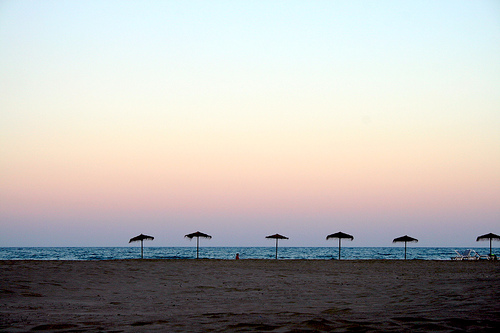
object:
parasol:
[265, 233, 289, 259]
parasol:
[129, 233, 154, 259]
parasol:
[184, 231, 212, 259]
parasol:
[326, 232, 354, 261]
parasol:
[392, 234, 418, 260]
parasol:
[476, 233, 500, 260]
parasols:
[129, 230, 500, 260]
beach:
[0, 259, 500, 333]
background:
[0, 0, 500, 333]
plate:
[0, 246, 499, 267]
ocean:
[0, 246, 500, 262]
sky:
[0, 0, 499, 247]